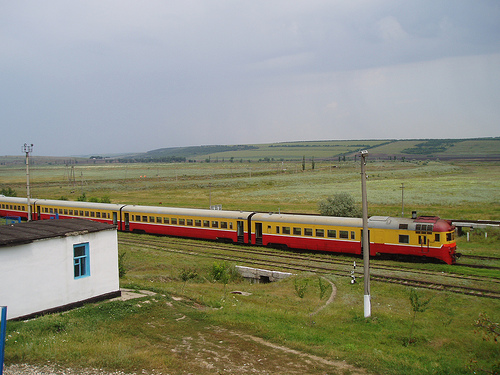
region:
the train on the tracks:
[5, 189, 450, 265]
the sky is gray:
[108, 44, 198, 107]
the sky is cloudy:
[370, 22, 449, 85]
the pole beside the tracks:
[345, 143, 387, 320]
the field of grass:
[318, 152, 483, 214]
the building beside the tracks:
[2, 208, 146, 318]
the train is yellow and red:
[145, 197, 480, 277]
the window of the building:
[64, 242, 94, 282]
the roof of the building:
[11, 222, 120, 245]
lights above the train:
[18, 140, 42, 162]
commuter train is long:
[0, 193, 456, 264]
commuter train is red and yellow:
[0, 193, 457, 266]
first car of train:
[249, 212, 457, 266]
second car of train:
[120, 202, 255, 245]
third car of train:
[34, 197, 127, 230]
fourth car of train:
[0, 193, 33, 218]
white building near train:
[1, 216, 123, 323]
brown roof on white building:
[1, 217, 117, 247]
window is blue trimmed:
[72, 241, 90, 278]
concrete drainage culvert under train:
[232, 263, 295, 285]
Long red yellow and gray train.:
[1, 194, 457, 260]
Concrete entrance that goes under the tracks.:
[231, 263, 297, 287]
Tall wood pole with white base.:
[357, 149, 375, 321]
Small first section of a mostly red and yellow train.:
[364, 212, 459, 263]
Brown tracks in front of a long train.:
[454, 247, 499, 267]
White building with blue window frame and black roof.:
[1, 212, 121, 327]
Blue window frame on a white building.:
[70, 240, 92, 279]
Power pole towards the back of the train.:
[22, 140, 33, 222]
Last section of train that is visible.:
[0, 192, 37, 222]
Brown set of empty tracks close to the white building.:
[118, 235, 498, 302]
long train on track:
[146, 192, 445, 259]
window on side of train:
[389, 227, 411, 248]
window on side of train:
[337, 227, 351, 242]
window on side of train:
[326, 225, 339, 238]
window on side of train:
[311, 224, 326, 236]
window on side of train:
[303, 226, 313, 236]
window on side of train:
[292, 225, 302, 237]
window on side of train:
[279, 224, 289, 232]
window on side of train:
[219, 217, 231, 226]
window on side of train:
[219, 219, 226, 229]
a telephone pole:
[346, 143, 399, 322]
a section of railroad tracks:
[374, 263, 495, 296]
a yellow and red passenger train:
[14, 189, 464, 263]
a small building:
[0, 203, 150, 314]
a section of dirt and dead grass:
[92, 290, 319, 374]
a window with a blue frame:
[64, 233, 104, 278]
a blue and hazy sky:
[34, 0, 491, 128]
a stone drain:
[225, 260, 285, 290]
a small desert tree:
[382, 273, 442, 350]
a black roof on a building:
[3, 213, 113, 241]